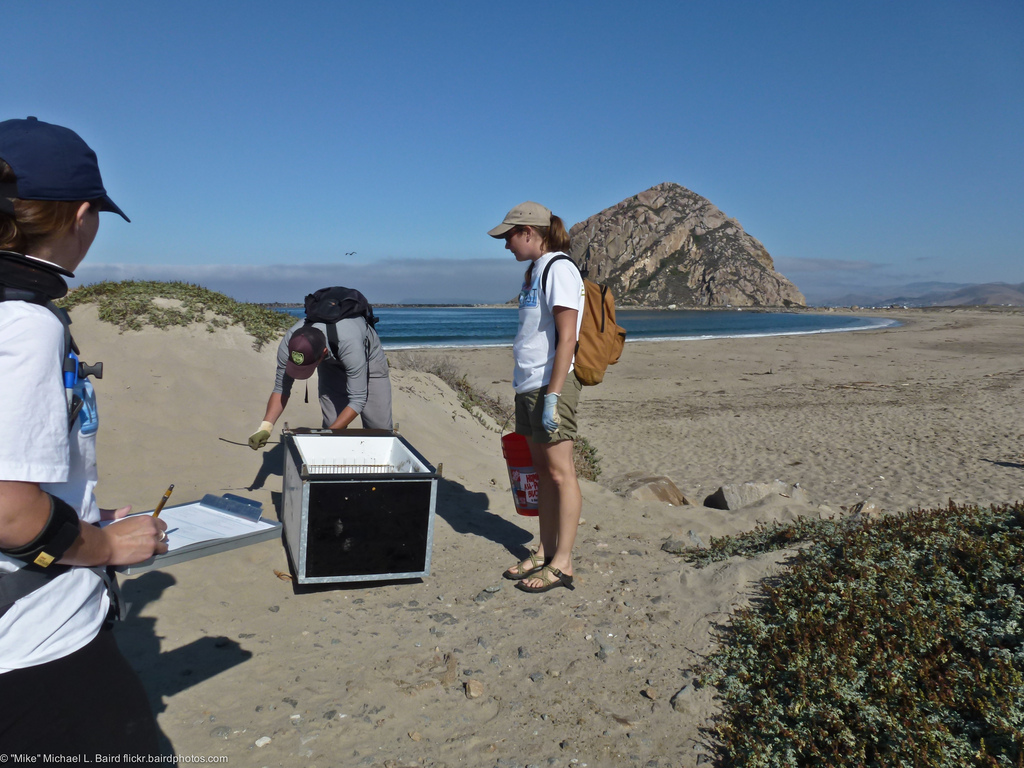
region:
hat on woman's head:
[482, 205, 555, 244]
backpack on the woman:
[577, 279, 638, 385]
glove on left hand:
[534, 393, 576, 441]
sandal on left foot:
[517, 558, 584, 594]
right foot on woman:
[506, 540, 545, 585]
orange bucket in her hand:
[476, 423, 550, 528]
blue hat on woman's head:
[3, 116, 146, 216]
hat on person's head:
[275, 328, 321, 392]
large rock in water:
[566, 186, 804, 314]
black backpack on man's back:
[302, 280, 388, 326]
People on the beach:
[2, 92, 721, 731]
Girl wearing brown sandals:
[464, 190, 664, 628]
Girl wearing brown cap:
[468, 193, 645, 628]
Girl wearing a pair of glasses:
[451, 198, 673, 620]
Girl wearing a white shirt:
[470, 195, 667, 632]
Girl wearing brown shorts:
[448, 177, 702, 652]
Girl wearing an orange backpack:
[467, 195, 663, 604]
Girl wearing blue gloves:
[458, 195, 656, 606]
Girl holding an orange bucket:
[458, 171, 662, 614]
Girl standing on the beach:
[442, 183, 680, 643]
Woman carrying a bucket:
[456, 195, 616, 614]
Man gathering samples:
[201, 275, 443, 608]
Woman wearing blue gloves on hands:
[456, 184, 635, 625]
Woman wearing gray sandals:
[453, 172, 603, 667]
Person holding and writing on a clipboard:
[0, 74, 304, 761]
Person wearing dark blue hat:
[0, 52, 315, 749]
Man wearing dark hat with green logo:
[187, 269, 432, 470]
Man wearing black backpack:
[200, 251, 415, 482]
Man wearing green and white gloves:
[194, 280, 460, 493]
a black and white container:
[278, 405, 476, 608]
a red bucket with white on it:
[498, 424, 565, 532]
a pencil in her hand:
[92, 471, 172, 592]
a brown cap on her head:
[492, 187, 557, 254]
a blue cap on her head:
[3, 110, 144, 238]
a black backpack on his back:
[274, 275, 380, 340]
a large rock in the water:
[520, 165, 840, 333]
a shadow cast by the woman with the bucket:
[403, 408, 543, 582]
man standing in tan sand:
[245, 268, 397, 428]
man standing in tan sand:
[11, 119, 212, 759]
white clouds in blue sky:
[283, 7, 391, 112]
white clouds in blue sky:
[517, 4, 595, 82]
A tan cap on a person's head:
[490, 202, 551, 240]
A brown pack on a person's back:
[576, 278, 621, 378]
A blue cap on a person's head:
[4, 118, 126, 221]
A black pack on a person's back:
[299, 282, 385, 330]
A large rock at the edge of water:
[544, 173, 804, 316]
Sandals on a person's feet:
[504, 551, 566, 593]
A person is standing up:
[482, 196, 603, 630]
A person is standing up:
[3, 125, 194, 748]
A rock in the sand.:
[525, 664, 541, 687]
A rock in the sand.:
[512, 640, 541, 661]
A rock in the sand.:
[599, 637, 622, 656]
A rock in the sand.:
[283, 689, 303, 705]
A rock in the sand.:
[321, 708, 326, 724]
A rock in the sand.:
[268, 596, 291, 613]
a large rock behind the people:
[568, 181, 775, 315]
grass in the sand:
[716, 537, 982, 747]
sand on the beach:
[654, 323, 1009, 542]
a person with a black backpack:
[281, 290, 376, 408]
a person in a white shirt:
[9, 116, 180, 743]